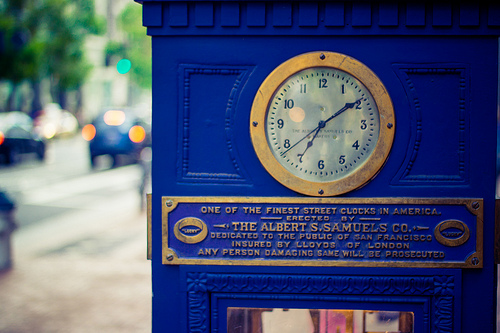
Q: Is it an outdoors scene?
A: Yes, it is outdoors.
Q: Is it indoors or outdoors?
A: It is outdoors.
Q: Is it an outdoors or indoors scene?
A: It is outdoors.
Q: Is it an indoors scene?
A: No, it is outdoors.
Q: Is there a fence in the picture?
A: No, there are no fences.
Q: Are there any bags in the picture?
A: No, there are no bags.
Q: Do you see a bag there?
A: No, there are no bags.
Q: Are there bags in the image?
A: No, there are no bags.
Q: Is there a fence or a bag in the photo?
A: No, there are no bags or fences.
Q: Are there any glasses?
A: No, there are no glasses.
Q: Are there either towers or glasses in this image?
A: No, there are no glasses or towers.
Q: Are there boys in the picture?
A: No, there are no boys.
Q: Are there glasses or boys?
A: No, there are no boys or glasses.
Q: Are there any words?
A: Yes, there are words.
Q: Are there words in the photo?
A: Yes, there are words.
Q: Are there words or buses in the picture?
A: Yes, there are words.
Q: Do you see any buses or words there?
A: Yes, there are words.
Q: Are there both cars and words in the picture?
A: Yes, there are both words and a car.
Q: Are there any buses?
A: No, there are no buses.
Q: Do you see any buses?
A: No, there are no buses.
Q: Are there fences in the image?
A: No, there are no fences.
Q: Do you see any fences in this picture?
A: No, there are no fences.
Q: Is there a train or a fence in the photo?
A: No, there are no fences or trains.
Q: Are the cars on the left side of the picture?
A: Yes, the cars are on the left of the image.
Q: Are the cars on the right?
A: No, the cars are on the left of the image.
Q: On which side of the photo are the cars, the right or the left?
A: The cars are on the left of the image.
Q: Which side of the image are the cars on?
A: The cars are on the left of the image.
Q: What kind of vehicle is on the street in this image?
A: The vehicles are cars.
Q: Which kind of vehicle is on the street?
A: The vehicles are cars.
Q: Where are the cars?
A: The cars are on the street.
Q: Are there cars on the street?
A: Yes, there are cars on the street.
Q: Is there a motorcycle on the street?
A: No, there are cars on the street.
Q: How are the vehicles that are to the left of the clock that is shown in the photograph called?
A: The vehicles are cars.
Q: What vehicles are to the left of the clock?
A: The vehicles are cars.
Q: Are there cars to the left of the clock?
A: Yes, there are cars to the left of the clock.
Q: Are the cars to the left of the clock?
A: Yes, the cars are to the left of the clock.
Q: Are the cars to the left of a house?
A: No, the cars are to the left of the clock.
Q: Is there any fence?
A: No, there are no fences.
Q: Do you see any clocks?
A: Yes, there is a clock.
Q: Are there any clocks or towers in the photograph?
A: Yes, there is a clock.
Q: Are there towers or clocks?
A: Yes, there is a clock.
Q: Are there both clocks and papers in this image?
A: No, there is a clock but no papers.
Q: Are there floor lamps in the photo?
A: No, there are no floor lamps.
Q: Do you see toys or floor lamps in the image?
A: No, there are no floor lamps or toys.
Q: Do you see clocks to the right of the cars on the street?
A: Yes, there is a clock to the right of the cars.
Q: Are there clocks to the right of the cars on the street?
A: Yes, there is a clock to the right of the cars.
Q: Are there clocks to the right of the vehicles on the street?
A: Yes, there is a clock to the right of the cars.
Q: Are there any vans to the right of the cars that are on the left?
A: No, there is a clock to the right of the cars.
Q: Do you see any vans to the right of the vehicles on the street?
A: No, there is a clock to the right of the cars.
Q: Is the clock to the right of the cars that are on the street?
A: Yes, the clock is to the right of the cars.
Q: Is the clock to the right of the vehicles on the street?
A: Yes, the clock is to the right of the cars.